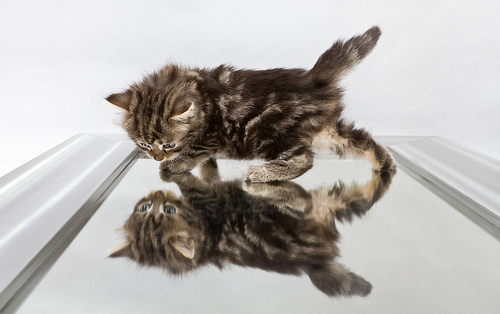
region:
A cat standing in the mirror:
[122, 13, 406, 173]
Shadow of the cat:
[135, 192, 375, 304]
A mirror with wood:
[430, 154, 497, 259]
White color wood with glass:
[430, 138, 467, 265]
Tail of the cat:
[320, 25, 409, 70]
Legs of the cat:
[185, 147, 319, 170]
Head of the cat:
[103, 68, 203, 161]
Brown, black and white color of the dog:
[99, 19, 411, 156]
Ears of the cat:
[106, 88, 199, 117]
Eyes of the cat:
[135, 138, 183, 153]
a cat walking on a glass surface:
[118, 35, 413, 208]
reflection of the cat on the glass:
[111, 161, 392, 303]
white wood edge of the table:
[0, 124, 119, 238]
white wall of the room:
[20, 8, 95, 97]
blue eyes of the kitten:
[128, 134, 183, 160]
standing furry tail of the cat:
[311, 20, 388, 106]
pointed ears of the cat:
[100, 83, 200, 120]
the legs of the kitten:
[163, 135, 403, 184]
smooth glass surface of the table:
[171, 181, 418, 281]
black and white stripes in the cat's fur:
[208, 84, 323, 151]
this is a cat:
[127, 32, 335, 144]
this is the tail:
[314, 38, 396, 60]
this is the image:
[123, 188, 358, 288]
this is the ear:
[171, 99, 210, 124]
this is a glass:
[130, 273, 230, 310]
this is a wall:
[391, 20, 484, 117]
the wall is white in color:
[411, 23, 496, 90]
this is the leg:
[176, 148, 215, 187]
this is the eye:
[160, 199, 182, 215]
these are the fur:
[171, 151, 186, 166]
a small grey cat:
[103, 17, 421, 177]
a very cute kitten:
[60, 11, 475, 206]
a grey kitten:
[86, 15, 414, 213]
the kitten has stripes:
[79, 21, 450, 203]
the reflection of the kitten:
[111, 160, 436, 300]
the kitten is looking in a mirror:
[75, 23, 442, 288]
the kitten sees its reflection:
[75, 10, 432, 265]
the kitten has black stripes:
[84, 28, 447, 215]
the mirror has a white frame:
[0, 123, 497, 311]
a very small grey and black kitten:
[102, 6, 429, 208]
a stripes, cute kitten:
[113, 76, 370, 189]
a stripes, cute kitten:
[112, 40, 468, 265]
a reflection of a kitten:
[120, 182, 342, 296]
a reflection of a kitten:
[114, 135, 374, 274]